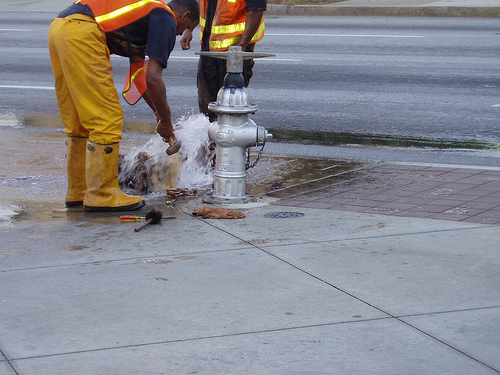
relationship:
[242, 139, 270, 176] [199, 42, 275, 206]
chains on fire hydrant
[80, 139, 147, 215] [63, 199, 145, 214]
boots with soles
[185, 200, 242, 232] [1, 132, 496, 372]
glove on ground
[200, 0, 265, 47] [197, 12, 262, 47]
vest with stripes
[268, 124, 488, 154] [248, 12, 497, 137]
puddle in road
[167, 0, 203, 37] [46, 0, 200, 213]
head of man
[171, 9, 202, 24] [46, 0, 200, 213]
ear of man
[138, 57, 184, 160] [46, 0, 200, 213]
arm of man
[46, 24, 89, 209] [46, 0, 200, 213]
leg of man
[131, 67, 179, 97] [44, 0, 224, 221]
elbow of man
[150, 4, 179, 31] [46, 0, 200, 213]
shoulder of man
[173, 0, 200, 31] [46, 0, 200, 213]
hair of man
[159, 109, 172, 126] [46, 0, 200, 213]
wrist of man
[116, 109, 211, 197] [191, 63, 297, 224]
water coming out of hydrant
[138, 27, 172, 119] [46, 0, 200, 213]
arm of man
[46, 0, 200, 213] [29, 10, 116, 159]
man wearing pants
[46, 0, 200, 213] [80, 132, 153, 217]
man wearing boot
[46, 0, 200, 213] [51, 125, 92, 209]
man wearing boot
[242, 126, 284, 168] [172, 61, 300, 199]
chain on hydrant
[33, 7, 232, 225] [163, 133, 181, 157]
man using tool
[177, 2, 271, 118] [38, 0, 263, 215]
man working on hydrant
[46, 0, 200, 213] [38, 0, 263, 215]
man working on hydrant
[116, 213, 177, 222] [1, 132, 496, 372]
screwdriver on ground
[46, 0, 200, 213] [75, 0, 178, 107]
man wearing outfit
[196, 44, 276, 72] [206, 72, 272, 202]
handle on hydrant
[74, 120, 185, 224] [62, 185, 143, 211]
boots on feet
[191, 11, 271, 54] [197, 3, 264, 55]
stripes on vest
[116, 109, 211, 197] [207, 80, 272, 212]
water gushing out of fire hydrant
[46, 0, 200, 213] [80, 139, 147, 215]
man wearing boots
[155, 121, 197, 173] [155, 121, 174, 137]
tool in hand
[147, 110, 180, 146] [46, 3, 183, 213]
hand of man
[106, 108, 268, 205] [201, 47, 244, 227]
water from fire hydrant